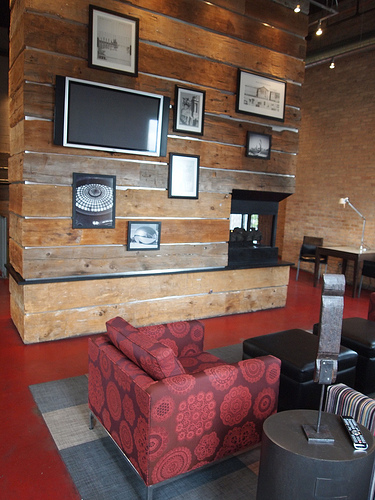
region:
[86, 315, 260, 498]
one person red chair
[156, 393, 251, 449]
pattern on the red chair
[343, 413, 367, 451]
the black remote control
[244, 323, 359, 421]
the dark colored ottoman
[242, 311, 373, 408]
two dark colored ottomans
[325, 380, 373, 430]
arm rest of a striped sofa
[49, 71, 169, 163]
a tv mounted on the wall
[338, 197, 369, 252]
a silver table lamp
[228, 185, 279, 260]
a black fire place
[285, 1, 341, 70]
the turned on ceiling lights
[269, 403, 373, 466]
a remote on a black round table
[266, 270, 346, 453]
a modern sculpture on a round black table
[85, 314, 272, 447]
a red armchair with floral patterns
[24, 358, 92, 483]
a checkered white and blue rug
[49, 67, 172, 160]
a flat screen TV on a wood wall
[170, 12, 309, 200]
a bunch a framed black and white photos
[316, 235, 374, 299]
a wood table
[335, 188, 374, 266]
a silver lamp on a wood table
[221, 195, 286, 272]
a black fireplace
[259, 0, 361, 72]
light fixtures hanging from the ceiling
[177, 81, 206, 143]
a picture on the wall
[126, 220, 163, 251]
a picture on the wall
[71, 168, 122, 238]
a picture on the wall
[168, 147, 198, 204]
a picture on the wall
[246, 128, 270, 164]
a picture on the wall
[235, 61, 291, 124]
a picture on the wall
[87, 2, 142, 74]
a picture on the wall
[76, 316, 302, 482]
Red chair in a room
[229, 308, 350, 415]
Black ottoman in a room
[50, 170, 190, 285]
Pictures on a wall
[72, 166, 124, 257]
Black and white picture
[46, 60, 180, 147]
TV on a wall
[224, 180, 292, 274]
Fireplace in a room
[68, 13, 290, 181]
Pictures on a brown wall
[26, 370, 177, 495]
Gray carpet on a floor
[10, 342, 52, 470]
Red floor in a room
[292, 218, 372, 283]
Table in a room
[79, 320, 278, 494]
red chair with print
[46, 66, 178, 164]
flat screen television on wall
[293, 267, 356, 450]
sculpture on round table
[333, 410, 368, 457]
remote control on table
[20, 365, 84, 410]
rug on red floor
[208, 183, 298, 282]
fireplace in corner of wall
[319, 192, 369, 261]
lamp on square table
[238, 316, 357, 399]
brown leather ottoman in front of chair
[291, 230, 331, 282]
chair in front of brick wall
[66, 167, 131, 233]
picture in black frame